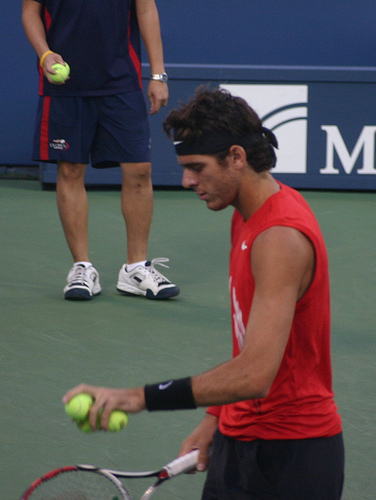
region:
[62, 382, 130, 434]
Man has three balls in his hand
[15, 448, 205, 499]
Man has a racket in his other hand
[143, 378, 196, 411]
Black wristband with nike logo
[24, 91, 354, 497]
Man getting ready to play tennis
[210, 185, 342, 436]
Man is wearing a red shirt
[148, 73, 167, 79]
Silver wrist watch on man's hand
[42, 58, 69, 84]
Man is holding a ball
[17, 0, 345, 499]
Two men on tennis court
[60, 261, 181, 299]
Man wearing blue and white sneakers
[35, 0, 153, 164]
Man wearing blue and red shirt and shorts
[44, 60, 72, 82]
Tennis ball in man's hand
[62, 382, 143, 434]
Man's hand full of tennis balls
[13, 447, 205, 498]
Tennis racquet in man's hand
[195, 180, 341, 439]
Red sleeveless shirt on man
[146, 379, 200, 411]
Black armband with Nike logo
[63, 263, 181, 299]
White tennis shoes on man's feet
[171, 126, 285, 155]
Black headband around man's head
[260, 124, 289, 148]
Knot in black headband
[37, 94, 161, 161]
Dark blue shorts with red stripes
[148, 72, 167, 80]
Silver watch on man's hand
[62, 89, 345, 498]
a male tennis player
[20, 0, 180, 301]
a male tennis player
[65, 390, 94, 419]
a bright yellow tennis ball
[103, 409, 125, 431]
a bright yellow tennis ball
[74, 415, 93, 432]
a bright yellow tennis ball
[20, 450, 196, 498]
a red and white tennis racket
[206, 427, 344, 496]
a black pair of men's shorts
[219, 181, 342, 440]
a bright red tank top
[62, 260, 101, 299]
a blue and white tennis shoe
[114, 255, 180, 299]
a blue and white tennis shoe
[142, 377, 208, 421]
the wrist band is black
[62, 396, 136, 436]
the balls are four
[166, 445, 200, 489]
the handle is white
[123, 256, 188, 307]
the shoes are black and white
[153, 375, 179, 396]
niki logo is on the band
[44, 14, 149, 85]
the top is black and red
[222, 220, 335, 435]
the vest is red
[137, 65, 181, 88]
watch is on the wrist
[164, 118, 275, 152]
head band is on the forehead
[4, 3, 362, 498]
the game is tennis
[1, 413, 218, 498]
Tennis racket in man's right hand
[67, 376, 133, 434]
Three tennis balls in man's left hand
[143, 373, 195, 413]
Nike-logo sweatband on man's wrist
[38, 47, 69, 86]
Tennis ball in man's hand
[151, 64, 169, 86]
Watch on man's left wrist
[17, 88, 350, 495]
Tennis player on court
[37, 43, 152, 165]
Blue shorts with red stripe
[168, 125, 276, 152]
Black headband on man's head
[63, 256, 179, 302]
Sneakers on man's feet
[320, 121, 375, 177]
The letter M on the poster